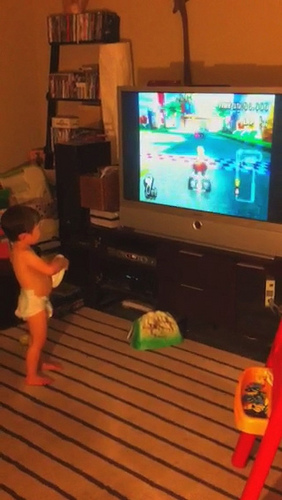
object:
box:
[78, 170, 120, 214]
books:
[88, 206, 120, 222]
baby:
[0, 196, 70, 388]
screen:
[138, 90, 277, 222]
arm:
[23, 248, 66, 279]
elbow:
[45, 260, 57, 277]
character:
[187, 140, 212, 194]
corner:
[137, 91, 147, 119]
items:
[75, 81, 90, 101]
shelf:
[45, 94, 101, 104]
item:
[127, 307, 183, 353]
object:
[191, 218, 202, 233]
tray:
[233, 362, 275, 441]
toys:
[242, 376, 272, 423]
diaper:
[14, 288, 54, 323]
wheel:
[48, 251, 67, 290]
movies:
[49, 114, 81, 131]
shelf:
[48, 36, 131, 47]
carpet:
[0, 306, 282, 500]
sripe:
[1, 451, 78, 499]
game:
[137, 89, 276, 224]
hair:
[0, 203, 42, 245]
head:
[0, 204, 41, 247]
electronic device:
[106, 242, 157, 271]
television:
[115, 82, 282, 265]